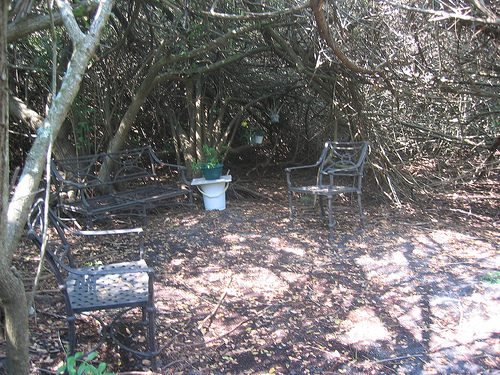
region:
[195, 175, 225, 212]
The white bucket next to the bench.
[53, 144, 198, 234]
The bench in the yard.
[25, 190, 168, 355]
The chair on the left.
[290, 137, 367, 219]
The chair on the right.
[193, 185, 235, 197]
The handle on the bucket.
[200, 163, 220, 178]
The green bowl on top of the bucket.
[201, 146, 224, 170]
The plant inside of the green bowl.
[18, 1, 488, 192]
The branches surrounding the area.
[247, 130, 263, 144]
The white bucket inside of the branches.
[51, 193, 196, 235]
The legs of the bench.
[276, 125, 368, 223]
Metal Chair near the trees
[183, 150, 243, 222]
Bucket with a plant on top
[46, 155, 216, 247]
Metal bench near the trees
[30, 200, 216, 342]
Metal bench in the woods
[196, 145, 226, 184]
Plant on a platform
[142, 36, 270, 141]
Trees over a bench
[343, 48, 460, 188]
Trees next to a bench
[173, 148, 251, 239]
White bucket on the ground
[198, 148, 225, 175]
Plant in a green pale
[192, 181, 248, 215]
White bucket with handle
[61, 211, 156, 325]
a chair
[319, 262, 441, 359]
shadows on the ground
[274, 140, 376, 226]
a grey chair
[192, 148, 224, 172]
a plant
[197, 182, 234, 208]
a white bucket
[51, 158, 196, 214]
a bench that is grey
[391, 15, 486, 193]
the tree branches are brown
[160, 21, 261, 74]
tree branches are tall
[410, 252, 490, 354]
the ground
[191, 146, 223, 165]
the plant is green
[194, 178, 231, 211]
white bucket turned into a table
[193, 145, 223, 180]
plant on the white table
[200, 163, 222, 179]
green pot for the plant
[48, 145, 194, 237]
black rod iron bench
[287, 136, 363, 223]
iron chair closer to the white table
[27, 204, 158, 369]
rod iron chair on the left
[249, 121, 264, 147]
plant in a white pot hanging from the trees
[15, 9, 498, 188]
several dead looking trees to make canopy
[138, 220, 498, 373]
dirt clearing with tree shadows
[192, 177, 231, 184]
white table top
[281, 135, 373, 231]
Chair on the ground.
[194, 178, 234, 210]
White bucket in the background.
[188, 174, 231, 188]
White board on the bucket.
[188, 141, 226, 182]
Planter on the bucket.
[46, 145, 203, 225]
Metal bench in the background.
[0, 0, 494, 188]
Trees in the background.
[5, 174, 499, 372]
Leaves covering the ground.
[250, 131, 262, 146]
White planter hanging from a tree.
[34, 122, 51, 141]
Green leaf on the tree.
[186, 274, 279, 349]
Branches on the ground.